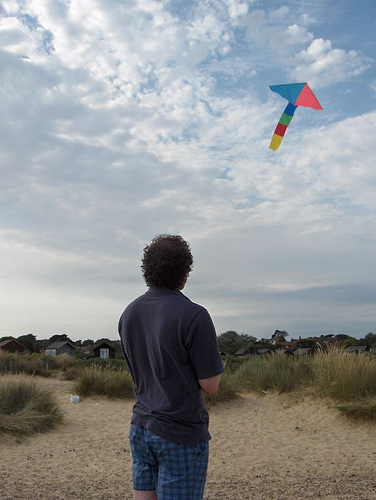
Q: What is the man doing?
A: Flying kites.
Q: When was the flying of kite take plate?
A: Daytime.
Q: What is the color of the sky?
A: Blue and white.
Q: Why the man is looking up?
A: To watch the kite.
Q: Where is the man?
A: In a field.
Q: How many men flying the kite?
A: One.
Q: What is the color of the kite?
A: Orange, blue, green, red and yellow.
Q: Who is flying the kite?
A: A man.